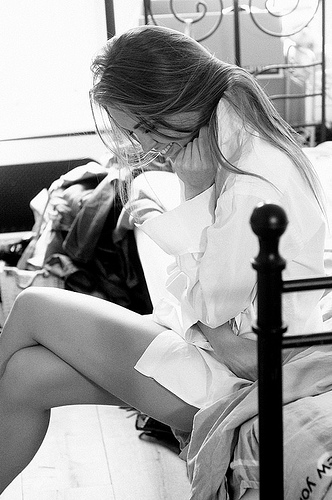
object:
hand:
[204, 316, 260, 381]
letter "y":
[302, 473, 317, 493]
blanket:
[179, 343, 331, 499]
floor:
[53, 409, 147, 498]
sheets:
[181, 397, 330, 496]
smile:
[149, 136, 185, 169]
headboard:
[103, 0, 328, 132]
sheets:
[179, 345, 331, 499]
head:
[89, 24, 220, 167]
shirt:
[132, 93, 327, 411]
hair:
[85, 25, 325, 200]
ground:
[134, 446, 169, 499]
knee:
[4, 342, 50, 405]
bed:
[0, 0, 332, 500]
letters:
[315, 457, 329, 478]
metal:
[251, 204, 331, 500]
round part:
[247, 202, 288, 270]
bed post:
[248, 199, 286, 498]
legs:
[0, 285, 201, 495]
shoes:
[133, 412, 189, 461]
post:
[249, 200, 289, 497]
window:
[0, 0, 111, 164]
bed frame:
[105, 0, 327, 148]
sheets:
[122, 140, 330, 354]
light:
[0, 6, 138, 143]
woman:
[1, 26, 325, 499]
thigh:
[0, 281, 196, 500]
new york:
[300, 453, 330, 498]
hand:
[172, 127, 216, 189]